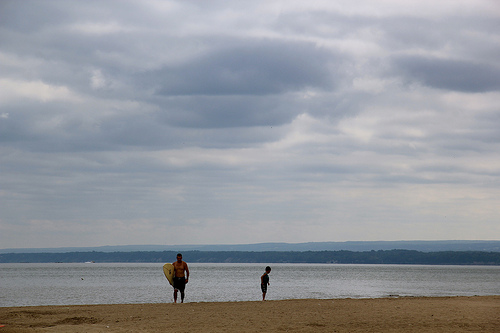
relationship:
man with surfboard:
[163, 255, 190, 304] [162, 263, 175, 283]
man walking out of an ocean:
[163, 255, 190, 304] [1, 264, 497, 305]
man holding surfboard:
[163, 255, 190, 304] [161, 263, 174, 285]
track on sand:
[305, 320, 327, 327] [0, 294, 498, 330]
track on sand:
[277, 324, 299, 329] [0, 294, 498, 330]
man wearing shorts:
[163, 255, 190, 304] [168, 280, 188, 295]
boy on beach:
[259, 265, 270, 301] [0, 296, 499, 331]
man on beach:
[163, 255, 190, 304] [0, 273, 495, 329]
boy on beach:
[259, 265, 270, 301] [0, 273, 495, 329]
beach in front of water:
[0, 296, 499, 331] [1, 259, 495, 308]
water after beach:
[281, 261, 494, 296] [0, 273, 495, 329]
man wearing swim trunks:
[163, 255, 190, 304] [170, 277, 191, 292]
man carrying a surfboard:
[163, 238, 202, 327] [153, 253, 179, 280]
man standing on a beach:
[163, 255, 190, 304] [72, 296, 499, 331]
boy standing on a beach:
[259, 265, 270, 298] [0, 296, 499, 331]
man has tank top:
[163, 255, 190, 304] [167, 253, 191, 285]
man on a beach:
[163, 255, 190, 304] [4, 280, 496, 329]